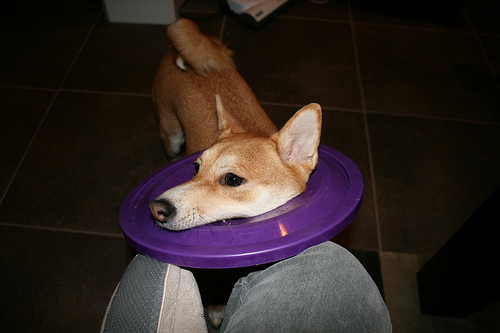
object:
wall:
[108, 1, 175, 24]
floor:
[0, 231, 99, 297]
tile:
[373, 181, 439, 250]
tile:
[366, 39, 459, 113]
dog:
[145, 18, 325, 230]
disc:
[117, 132, 367, 269]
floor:
[370, 5, 497, 177]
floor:
[3, 291, 89, 329]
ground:
[372, 135, 483, 194]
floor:
[53, 104, 127, 174]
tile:
[249, 22, 354, 101]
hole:
[156, 210, 171, 219]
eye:
[219, 172, 247, 187]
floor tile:
[374, 114, 496, 254]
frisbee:
[116, 139, 363, 269]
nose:
[148, 198, 177, 224]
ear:
[269, 103, 323, 172]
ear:
[215, 94, 248, 139]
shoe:
[99, 253, 208, 332]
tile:
[0, 146, 97, 205]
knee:
[230, 242, 388, 313]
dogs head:
[144, 94, 324, 234]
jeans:
[251, 267, 355, 331]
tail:
[165, 19, 235, 79]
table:
[370, 115, 500, 323]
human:
[220, 241, 394, 331]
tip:
[150, 206, 159, 214]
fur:
[178, 75, 198, 105]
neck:
[248, 205, 289, 219]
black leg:
[427, 233, 485, 315]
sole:
[99, 254, 167, 333]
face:
[148, 133, 303, 231]